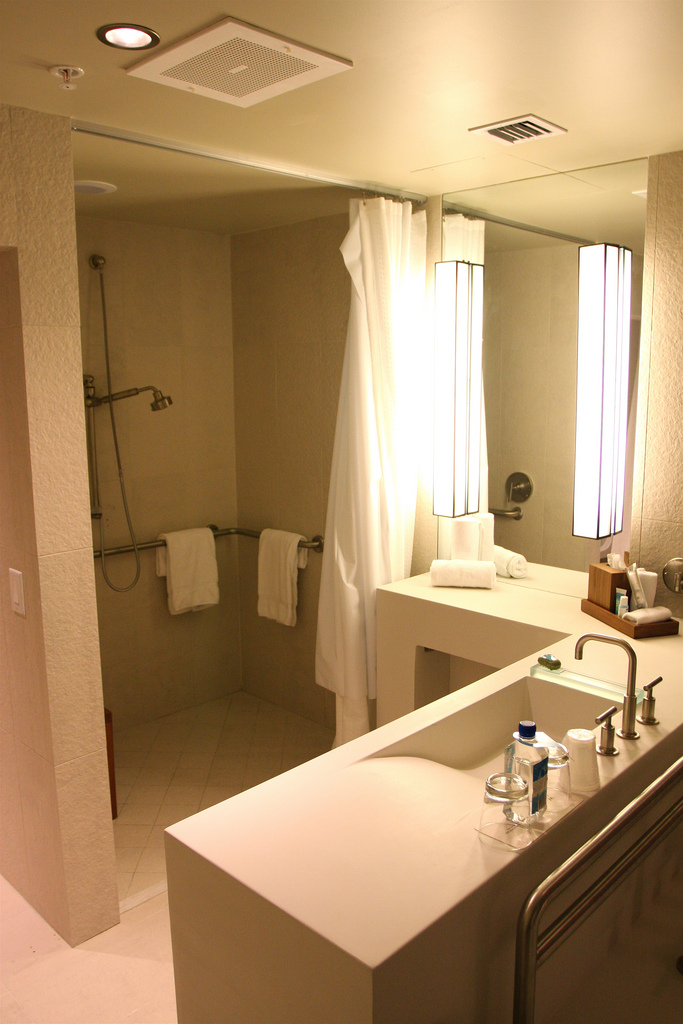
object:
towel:
[431, 559, 495, 588]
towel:
[156, 530, 218, 615]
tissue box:
[581, 550, 676, 640]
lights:
[632, 190, 647, 197]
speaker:
[129, 20, 353, 116]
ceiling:
[3, 5, 681, 202]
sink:
[367, 665, 654, 826]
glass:
[478, 772, 528, 848]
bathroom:
[0, 5, 680, 1023]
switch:
[8, 566, 25, 615]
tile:
[228, 687, 260, 710]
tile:
[257, 703, 287, 725]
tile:
[251, 731, 285, 754]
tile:
[245, 740, 281, 772]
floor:
[0, 678, 356, 1019]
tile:
[182, 734, 220, 753]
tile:
[151, 730, 191, 752]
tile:
[153, 804, 199, 825]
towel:
[257, 529, 309, 628]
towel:
[492, 544, 526, 577]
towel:
[451, 518, 479, 561]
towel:
[622, 606, 671, 625]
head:
[151, 391, 173, 411]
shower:
[67, 124, 388, 883]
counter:
[376, 570, 607, 730]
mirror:
[410, 160, 654, 571]